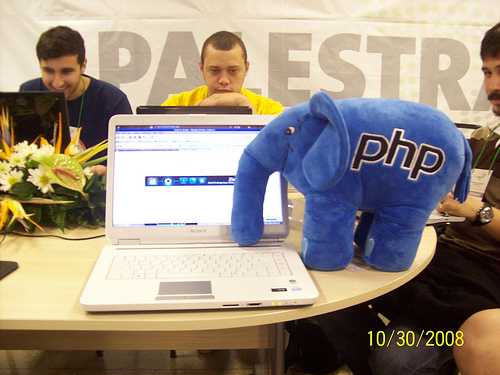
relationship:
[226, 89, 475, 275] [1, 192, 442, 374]
stuffed animal on a table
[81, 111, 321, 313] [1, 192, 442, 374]
laptop on a table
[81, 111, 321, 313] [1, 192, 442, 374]
laptop on table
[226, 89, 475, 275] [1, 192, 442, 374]
stuffed animal on table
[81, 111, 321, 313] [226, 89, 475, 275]
laptop next to stuffed animal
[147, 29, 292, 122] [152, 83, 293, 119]
man wearing shirt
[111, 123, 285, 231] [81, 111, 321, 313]
screen of laptop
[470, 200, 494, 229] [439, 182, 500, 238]
watch on arm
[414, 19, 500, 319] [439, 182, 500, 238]
man has arm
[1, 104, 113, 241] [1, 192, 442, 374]
flower arrangement on table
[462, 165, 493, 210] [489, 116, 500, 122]
name tag around neck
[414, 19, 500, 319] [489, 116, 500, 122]
man has neck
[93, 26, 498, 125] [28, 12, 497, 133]
letters on banner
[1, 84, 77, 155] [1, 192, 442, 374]
laptop on table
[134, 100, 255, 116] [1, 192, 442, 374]
laptop on table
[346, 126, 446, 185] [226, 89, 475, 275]
letters on stuffed animal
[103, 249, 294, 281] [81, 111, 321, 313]
keyboard on laptop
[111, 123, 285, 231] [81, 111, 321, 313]
screen on laptop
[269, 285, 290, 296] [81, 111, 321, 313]
lable on laptop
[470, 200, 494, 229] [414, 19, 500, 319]
watch on man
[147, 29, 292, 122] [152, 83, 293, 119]
man in a shirt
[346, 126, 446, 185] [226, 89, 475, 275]
letters on side of stuffed animal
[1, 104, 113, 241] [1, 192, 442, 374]
flower arrangement on a table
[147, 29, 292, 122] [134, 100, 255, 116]
man using a laptop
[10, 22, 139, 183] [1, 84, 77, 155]
man using a laptop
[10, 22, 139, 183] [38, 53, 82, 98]
man has face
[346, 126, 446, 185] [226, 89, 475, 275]
letters on a stuffed animal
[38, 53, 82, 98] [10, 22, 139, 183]
face of a man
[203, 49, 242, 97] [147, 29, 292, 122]
face of a man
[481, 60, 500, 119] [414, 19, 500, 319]
face of a man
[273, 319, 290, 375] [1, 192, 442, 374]
post on a table